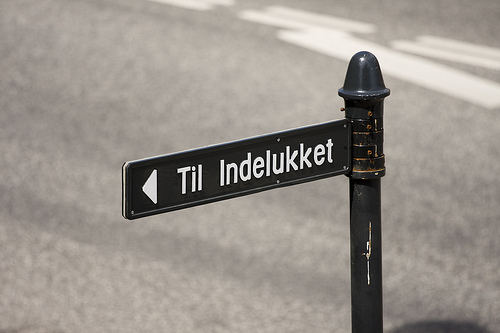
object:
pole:
[337, 51, 391, 332]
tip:
[332, 46, 393, 102]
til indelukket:
[120, 119, 348, 221]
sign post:
[118, 49, 391, 333]